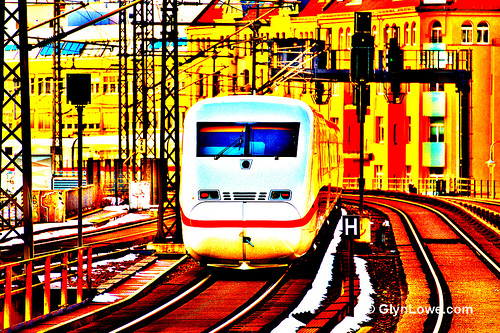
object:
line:
[177, 207, 214, 232]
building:
[182, 0, 498, 195]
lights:
[306, 11, 406, 121]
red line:
[281, 212, 313, 232]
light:
[196, 187, 220, 203]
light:
[266, 185, 294, 203]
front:
[181, 98, 307, 266]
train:
[178, 92, 346, 274]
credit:
[372, 292, 479, 324]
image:
[4, 3, 489, 327]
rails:
[101, 263, 292, 331]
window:
[198, 122, 247, 154]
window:
[249, 122, 297, 154]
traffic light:
[386, 39, 404, 103]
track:
[103, 262, 297, 331]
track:
[428, 282, 499, 331]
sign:
[339, 213, 361, 318]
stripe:
[301, 195, 319, 230]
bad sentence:
[42, 6, 452, 157]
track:
[358, 183, 490, 330]